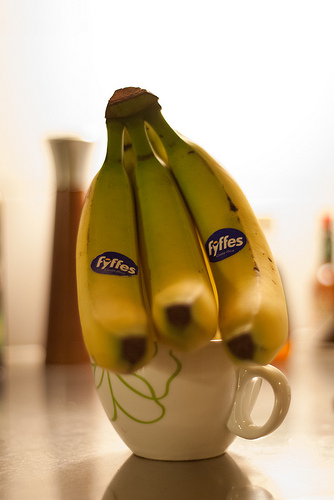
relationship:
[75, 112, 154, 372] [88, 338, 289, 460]
banana sitting atop cup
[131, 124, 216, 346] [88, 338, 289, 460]
banana sitting atop cup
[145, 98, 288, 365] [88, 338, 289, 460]
banana sitting atop cup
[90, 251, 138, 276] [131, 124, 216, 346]
label on banana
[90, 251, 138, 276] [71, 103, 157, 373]
label on banana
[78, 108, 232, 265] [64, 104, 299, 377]
three ripe yellow bananas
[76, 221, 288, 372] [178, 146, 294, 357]
bunch of ripe banana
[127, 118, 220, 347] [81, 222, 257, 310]
banana with blue stickers on them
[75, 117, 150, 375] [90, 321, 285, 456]
banana sitting on a cup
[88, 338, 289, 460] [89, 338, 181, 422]
cup white with green flower design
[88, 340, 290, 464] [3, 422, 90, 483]
cup on table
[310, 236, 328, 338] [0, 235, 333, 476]
bottle of tabasco sauce in background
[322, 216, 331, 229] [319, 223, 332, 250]
lid of tabasco sauce red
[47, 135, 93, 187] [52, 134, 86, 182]
lid of ketchup bottle white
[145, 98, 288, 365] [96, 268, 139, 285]
banana with blue label "fyffes"